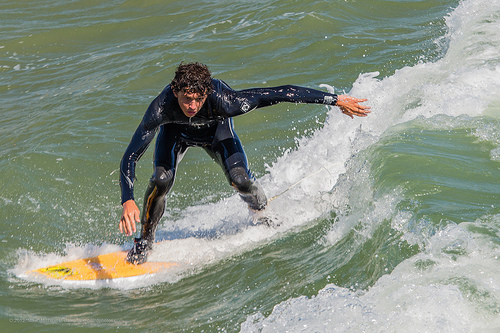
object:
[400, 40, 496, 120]
wave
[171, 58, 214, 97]
hair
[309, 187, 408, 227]
wave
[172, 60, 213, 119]
head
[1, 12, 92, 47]
waves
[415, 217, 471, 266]
ocean waves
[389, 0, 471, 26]
water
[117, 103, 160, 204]
arm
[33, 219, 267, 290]
surfboard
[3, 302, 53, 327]
water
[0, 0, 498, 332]
ocean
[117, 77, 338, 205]
black wetsuit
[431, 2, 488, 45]
waves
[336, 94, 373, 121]
hand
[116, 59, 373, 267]
man